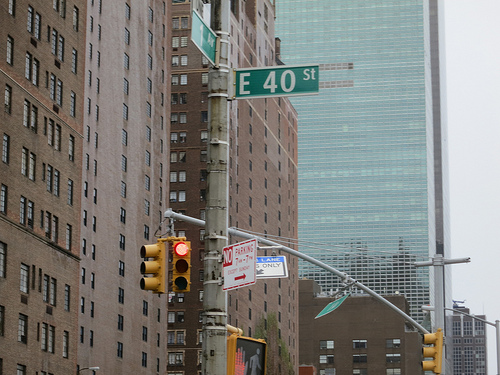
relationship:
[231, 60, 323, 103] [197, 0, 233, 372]
sign on side of pole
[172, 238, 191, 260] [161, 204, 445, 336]
light hanging on pole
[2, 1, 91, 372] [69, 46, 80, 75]
building has window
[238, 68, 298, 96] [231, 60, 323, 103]
e 40 written on sign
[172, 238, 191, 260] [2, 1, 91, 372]
light in front of building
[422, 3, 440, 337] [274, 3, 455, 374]
line on edge of building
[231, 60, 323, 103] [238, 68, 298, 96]
sign reads e 40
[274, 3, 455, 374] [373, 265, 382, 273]
building has window